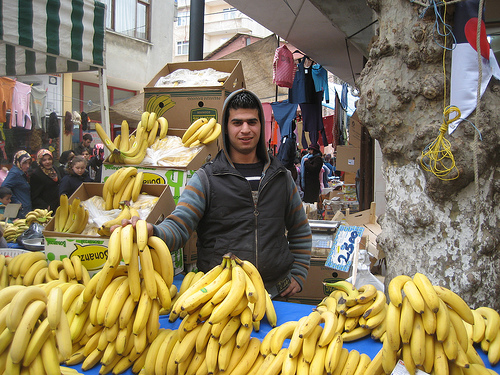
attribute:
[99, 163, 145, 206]
bananas — ripe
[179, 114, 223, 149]
bananas — ripe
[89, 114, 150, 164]
bananas — ripe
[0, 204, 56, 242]
bananas — ripe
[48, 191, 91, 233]
bananas — ripe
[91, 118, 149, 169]
bananas — ripe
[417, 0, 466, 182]
cord — yellow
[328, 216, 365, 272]
price tag — blue and white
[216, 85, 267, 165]
hoodie — brown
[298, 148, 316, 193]
scarf — blue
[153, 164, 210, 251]
sleeves — striped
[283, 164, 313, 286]
sleeves — striped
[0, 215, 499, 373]
bananas — ripe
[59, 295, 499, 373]
cover — blue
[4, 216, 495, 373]
banana bunch — large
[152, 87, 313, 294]
hoodie — gray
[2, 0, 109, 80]
awning — green, white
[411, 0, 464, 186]
string — yellow, blue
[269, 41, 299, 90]
sweater — pink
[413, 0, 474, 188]
rope — yellow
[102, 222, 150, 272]
bananas — yellow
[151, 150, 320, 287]
shirt — gray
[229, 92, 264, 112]
hair — black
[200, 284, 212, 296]
sticker — green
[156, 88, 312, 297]
jacket — gray